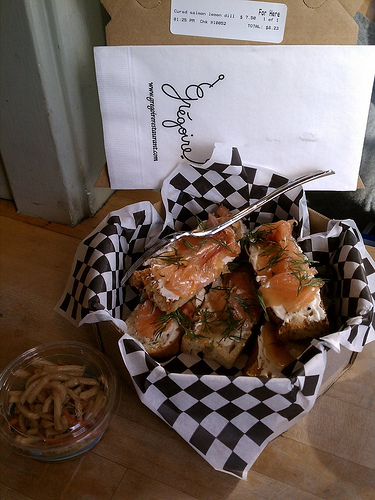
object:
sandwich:
[244, 219, 328, 334]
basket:
[100, 189, 375, 407]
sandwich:
[183, 269, 260, 361]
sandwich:
[135, 212, 252, 314]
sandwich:
[126, 297, 179, 357]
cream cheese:
[271, 291, 324, 322]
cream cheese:
[156, 280, 181, 307]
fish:
[250, 218, 325, 312]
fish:
[156, 207, 241, 297]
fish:
[208, 272, 261, 341]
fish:
[138, 298, 169, 335]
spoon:
[154, 170, 337, 260]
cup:
[0, 337, 121, 460]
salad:
[8, 356, 108, 441]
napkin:
[52, 142, 374, 482]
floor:
[0, 186, 375, 499]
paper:
[91, 45, 375, 191]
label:
[169, 0, 287, 44]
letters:
[165, 0, 284, 35]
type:
[148, 73, 223, 164]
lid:
[3, 339, 121, 457]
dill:
[245, 229, 331, 296]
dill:
[149, 250, 191, 269]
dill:
[150, 309, 193, 337]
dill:
[213, 306, 247, 346]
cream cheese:
[221, 256, 234, 267]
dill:
[208, 233, 236, 253]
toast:
[271, 308, 327, 330]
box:
[100, 1, 374, 43]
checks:
[169, 172, 191, 190]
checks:
[193, 177, 213, 198]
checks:
[215, 180, 236, 199]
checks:
[178, 192, 192, 206]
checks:
[132, 210, 152, 241]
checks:
[204, 185, 225, 203]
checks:
[226, 174, 247, 188]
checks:
[252, 168, 274, 188]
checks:
[200, 391, 229, 411]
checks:
[230, 393, 260, 411]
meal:
[4, 146, 370, 462]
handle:
[211, 168, 335, 235]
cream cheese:
[249, 240, 259, 267]